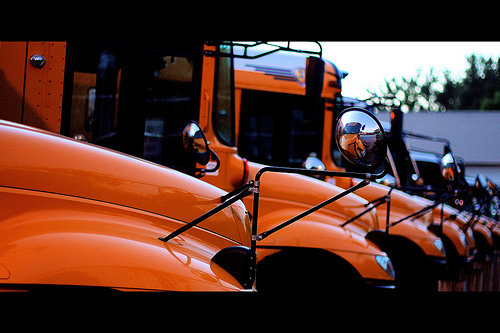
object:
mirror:
[331, 103, 388, 171]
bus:
[229, 38, 458, 293]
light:
[374, 250, 401, 280]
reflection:
[337, 119, 368, 160]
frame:
[437, 145, 467, 185]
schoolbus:
[2, 102, 260, 293]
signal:
[459, 230, 471, 250]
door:
[238, 91, 324, 171]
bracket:
[156, 164, 390, 288]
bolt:
[253, 251, 259, 255]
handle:
[202, 91, 215, 132]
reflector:
[333, 67, 351, 80]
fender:
[256, 214, 397, 290]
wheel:
[268, 258, 350, 297]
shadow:
[268, 187, 367, 231]